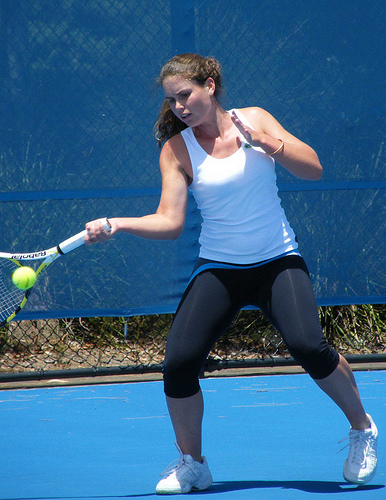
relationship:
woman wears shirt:
[88, 45, 374, 492] [177, 105, 301, 263]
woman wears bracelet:
[84, 52, 380, 495] [269, 133, 283, 156]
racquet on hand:
[0, 215, 113, 330] [80, 215, 118, 246]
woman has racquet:
[88, 45, 374, 492] [0, 215, 113, 330]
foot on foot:
[153, 445, 216, 498] [153, 445, 216, 498]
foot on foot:
[337, 414, 378, 486] [338, 409, 384, 487]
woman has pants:
[88, 45, 374, 492] [161, 257, 341, 400]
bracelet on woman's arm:
[263, 138, 287, 164] [247, 104, 348, 188]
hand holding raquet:
[85, 216, 118, 247] [0, 235, 76, 330]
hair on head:
[157, 51, 224, 141] [148, 54, 225, 135]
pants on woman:
[136, 246, 358, 401] [88, 45, 374, 492]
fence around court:
[2, 2, 383, 346] [5, 367, 383, 498]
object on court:
[9, 4, 377, 311] [8, 331, 372, 495]